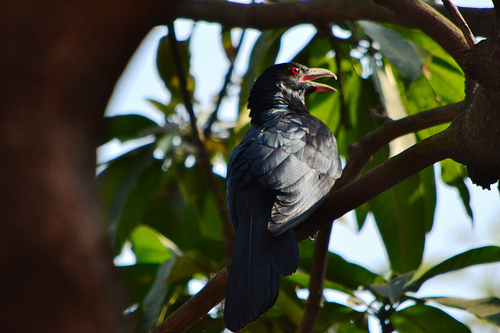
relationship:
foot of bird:
[309, 229, 320, 242] [206, 50, 388, 287]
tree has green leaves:
[1, 0, 226, 332] [387, 306, 469, 332]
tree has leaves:
[343, 1, 499, 332] [387, 306, 469, 332]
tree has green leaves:
[343, 1, 499, 332] [387, 306, 469, 332]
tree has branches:
[343, 1, 499, 332] [345, 129, 459, 209]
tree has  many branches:
[343, 1, 499, 332] [160, 1, 437, 31]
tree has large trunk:
[1, 0, 226, 332] [0, 1, 97, 332]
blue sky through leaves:
[97, 18, 242, 138] [324, 196, 499, 333]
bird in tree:
[223, 62, 340, 332] [1, 0, 226, 332]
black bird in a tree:
[223, 62, 340, 332] [1, 0, 226, 332]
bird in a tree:
[223, 62, 340, 332] [1, 0, 226, 332]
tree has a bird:
[1, 0, 226, 332] [223, 62, 340, 332]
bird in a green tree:
[223, 62, 340, 332] [343, 1, 499, 332]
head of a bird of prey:
[248, 63, 338, 111] [223, 62, 340, 332]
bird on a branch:
[223, 62, 340, 332] [345, 129, 459, 209]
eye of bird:
[292, 63, 300, 75] [223, 62, 340, 332]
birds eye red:
[223, 62, 340, 332] [292, 63, 300, 75]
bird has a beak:
[223, 62, 340, 332] [303, 69, 336, 82]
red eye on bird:
[292, 63, 300, 75] [223, 62, 340, 332]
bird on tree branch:
[223, 62, 340, 332] [345, 129, 459, 209]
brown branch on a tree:
[345, 129, 459, 209] [1, 0, 226, 332]